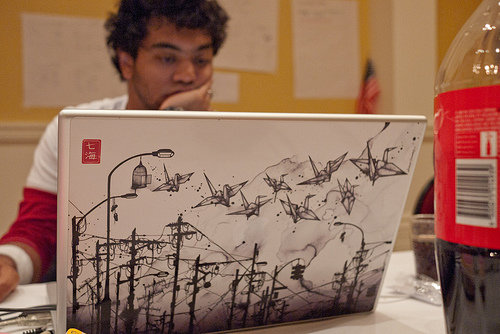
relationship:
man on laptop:
[0, 1, 231, 301] [52, 110, 430, 331]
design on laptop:
[65, 122, 415, 331] [52, 110, 430, 331]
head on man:
[110, 3, 227, 111] [0, 1, 231, 301]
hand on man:
[160, 78, 214, 111] [0, 1, 231, 301]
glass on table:
[408, 211, 439, 286] [0, 247, 448, 334]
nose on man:
[170, 58, 200, 86] [0, 1, 231, 301]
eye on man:
[154, 53, 179, 64] [0, 1, 231, 301]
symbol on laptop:
[81, 137, 102, 166] [52, 110, 430, 331]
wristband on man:
[1, 242, 37, 284] [0, 1, 231, 301]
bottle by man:
[431, 1, 499, 333] [0, 1, 231, 301]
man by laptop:
[0, 1, 231, 301] [52, 110, 430, 331]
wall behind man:
[2, 1, 499, 215] [0, 1, 231, 301]